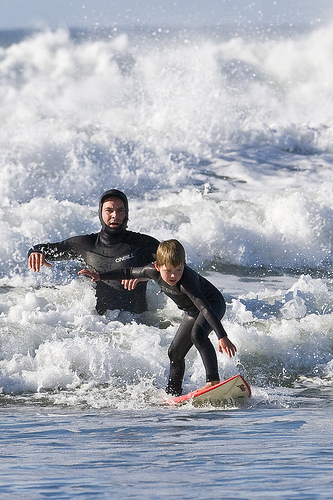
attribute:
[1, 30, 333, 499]
water — blue, splashing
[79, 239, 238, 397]
boy — young, surfing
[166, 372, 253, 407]
board — white, red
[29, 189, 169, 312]
wetsuit — black